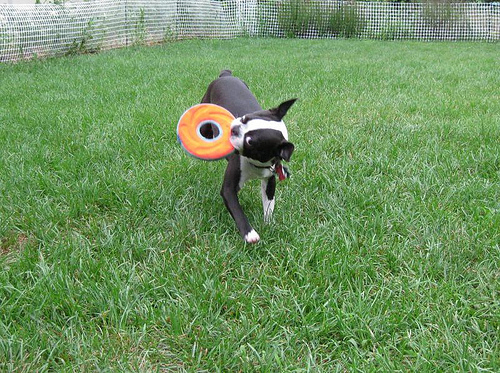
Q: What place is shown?
A: It is a field.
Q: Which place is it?
A: It is a field.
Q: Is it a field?
A: Yes, it is a field.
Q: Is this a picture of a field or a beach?
A: It is showing a field.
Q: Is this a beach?
A: No, it is a field.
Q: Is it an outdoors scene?
A: Yes, it is outdoors.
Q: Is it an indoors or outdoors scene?
A: It is outdoors.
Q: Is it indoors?
A: No, it is outdoors.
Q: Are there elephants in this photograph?
A: No, there are no elephants.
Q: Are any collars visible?
A: Yes, there is a collar.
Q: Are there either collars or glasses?
A: Yes, there is a collar.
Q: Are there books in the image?
A: No, there are no books.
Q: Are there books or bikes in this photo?
A: No, there are no books or bikes.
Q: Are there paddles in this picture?
A: No, there are no paddles.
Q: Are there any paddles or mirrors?
A: No, there are no paddles or mirrors.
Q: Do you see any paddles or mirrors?
A: No, there are no paddles or mirrors.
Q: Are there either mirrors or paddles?
A: No, there are no paddles or mirrors.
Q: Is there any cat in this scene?
A: No, there are no cats.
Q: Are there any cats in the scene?
A: No, there are no cats.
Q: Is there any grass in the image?
A: Yes, there is grass.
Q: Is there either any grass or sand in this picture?
A: Yes, there is grass.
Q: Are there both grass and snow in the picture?
A: No, there is grass but no snow.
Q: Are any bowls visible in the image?
A: No, there are no bowls.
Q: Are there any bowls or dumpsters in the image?
A: No, there are no bowls or dumpsters.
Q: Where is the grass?
A: The grass is in the yard.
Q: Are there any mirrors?
A: No, there are no mirrors.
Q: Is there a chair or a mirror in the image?
A: No, there are no mirrors or chairs.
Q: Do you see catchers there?
A: No, there are no catchers.